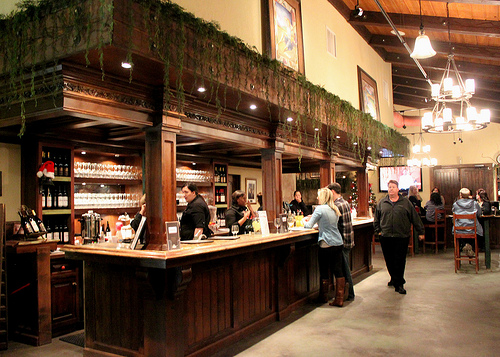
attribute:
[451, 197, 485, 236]
coat — blue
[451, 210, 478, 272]
chair — wooden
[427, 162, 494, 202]
door — wood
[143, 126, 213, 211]
column — wood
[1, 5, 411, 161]
ferns — decorative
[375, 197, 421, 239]
shirt — gray 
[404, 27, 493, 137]
lights — white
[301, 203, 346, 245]
shirt — blue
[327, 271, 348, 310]
boots — brown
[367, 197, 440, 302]
pants — dark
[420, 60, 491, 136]
chandelier — large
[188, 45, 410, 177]
plants — green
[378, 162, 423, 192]
television — flat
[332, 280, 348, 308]
leather boot — knee high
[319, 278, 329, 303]
leather boot — knee high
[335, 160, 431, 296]
man — large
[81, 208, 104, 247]
coffee urn — chrome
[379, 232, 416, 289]
pants — black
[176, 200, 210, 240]
shirt — black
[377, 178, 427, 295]
man — hefty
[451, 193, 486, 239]
top — blue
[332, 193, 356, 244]
shirt — plaid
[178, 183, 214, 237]
person — heavyset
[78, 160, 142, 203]
glasses — Upside down